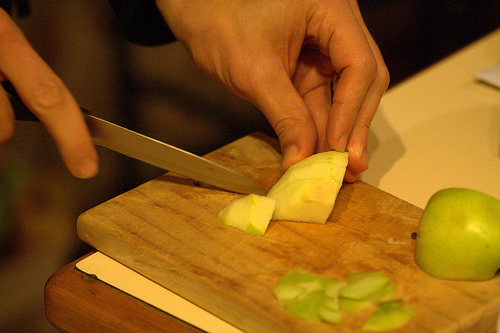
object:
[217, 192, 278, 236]
sliced piece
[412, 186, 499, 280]
apple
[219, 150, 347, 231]
apple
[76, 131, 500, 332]
cutting board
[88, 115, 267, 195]
metal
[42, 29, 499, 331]
table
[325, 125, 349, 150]
finger tip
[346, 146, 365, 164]
finger tip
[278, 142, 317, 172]
finger tip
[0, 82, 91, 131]
knife handle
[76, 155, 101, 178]
nail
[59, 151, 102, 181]
finger tip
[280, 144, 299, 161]
nail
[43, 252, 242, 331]
corner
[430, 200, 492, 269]
light reflection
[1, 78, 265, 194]
knife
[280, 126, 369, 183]
fingers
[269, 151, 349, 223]
piece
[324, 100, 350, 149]
finger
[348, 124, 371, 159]
finger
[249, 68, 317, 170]
finger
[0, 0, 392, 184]
person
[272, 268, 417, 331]
peel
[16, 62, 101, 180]
finger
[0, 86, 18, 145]
finger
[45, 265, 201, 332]
wooden edge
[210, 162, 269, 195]
tip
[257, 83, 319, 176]
thumb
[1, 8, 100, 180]
hand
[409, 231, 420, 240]
stem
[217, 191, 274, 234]
apple slicings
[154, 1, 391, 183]
hand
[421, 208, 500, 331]
corner